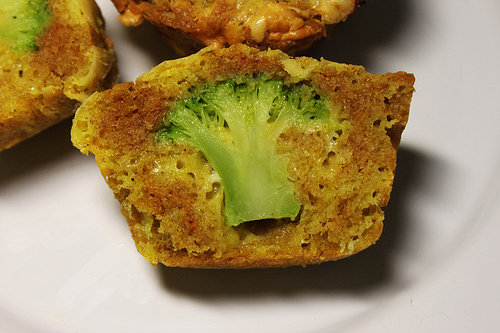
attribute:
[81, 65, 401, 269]
muffin — cut, half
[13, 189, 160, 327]
plate — white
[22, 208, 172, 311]
plate — white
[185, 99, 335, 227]
broccoli — green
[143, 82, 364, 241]
brocolli — green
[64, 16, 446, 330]
food — delicious, tasty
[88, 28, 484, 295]
food — hot looking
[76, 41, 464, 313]
food — tasty looking, sweet looking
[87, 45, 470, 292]
food — delicious looking, superb looking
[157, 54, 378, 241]
tree — green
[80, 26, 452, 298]
food — piece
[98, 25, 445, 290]
items — food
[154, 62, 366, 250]
brocolli — piece, green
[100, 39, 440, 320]
pastry — brown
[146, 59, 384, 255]
vegetable — green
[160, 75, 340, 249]
floret — brocolli, half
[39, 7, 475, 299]
pastries — bunch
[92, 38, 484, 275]
pastries — bunch, cut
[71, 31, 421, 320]
pastries — bunch, cut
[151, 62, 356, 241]
brocolli — green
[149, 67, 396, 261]
brocolli — green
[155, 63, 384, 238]
floret — brocolli, stem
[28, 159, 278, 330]
table — white